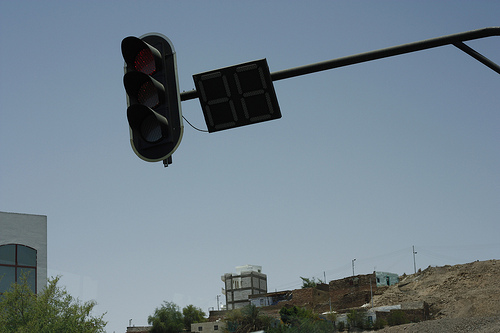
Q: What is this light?
A: A stop light.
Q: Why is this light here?
A: Intersection.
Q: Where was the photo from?
A: A car.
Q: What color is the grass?
A: Brown.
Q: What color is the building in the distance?
A: White.